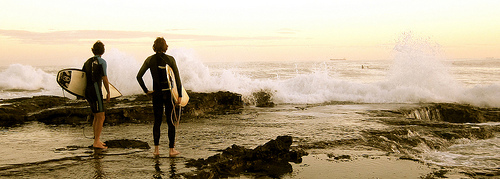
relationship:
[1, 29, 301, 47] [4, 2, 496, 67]
clouds in sky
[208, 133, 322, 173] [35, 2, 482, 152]
rock on beach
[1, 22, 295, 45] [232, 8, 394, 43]
clouds in sky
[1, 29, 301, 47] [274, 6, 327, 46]
clouds in sky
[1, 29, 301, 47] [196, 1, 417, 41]
clouds in sky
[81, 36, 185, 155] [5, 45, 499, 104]
men watching waves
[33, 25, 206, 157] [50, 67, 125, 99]
men carrying surfboards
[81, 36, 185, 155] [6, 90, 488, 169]
men are on beach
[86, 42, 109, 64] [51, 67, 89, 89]
man holding surfboard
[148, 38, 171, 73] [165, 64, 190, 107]
man holding board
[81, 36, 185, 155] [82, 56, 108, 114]
men are wearing gear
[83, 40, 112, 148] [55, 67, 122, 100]
man holding board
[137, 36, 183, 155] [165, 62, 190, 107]
man holding board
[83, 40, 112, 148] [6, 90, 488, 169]
man on beach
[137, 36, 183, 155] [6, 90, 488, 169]
man on beach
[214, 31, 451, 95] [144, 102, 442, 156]
wave on shore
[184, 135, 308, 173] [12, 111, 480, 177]
rock on beach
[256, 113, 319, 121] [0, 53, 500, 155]
ripple in wave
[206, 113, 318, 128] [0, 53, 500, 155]
ripple in wave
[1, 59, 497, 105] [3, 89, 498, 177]
water splashing on shore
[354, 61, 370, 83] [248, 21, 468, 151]
object in water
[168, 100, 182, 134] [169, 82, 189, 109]
cable hanging from surfboard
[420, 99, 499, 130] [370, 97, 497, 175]
depresion in ground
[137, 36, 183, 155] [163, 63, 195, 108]
man carrying board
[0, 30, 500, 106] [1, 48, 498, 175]
wave in water